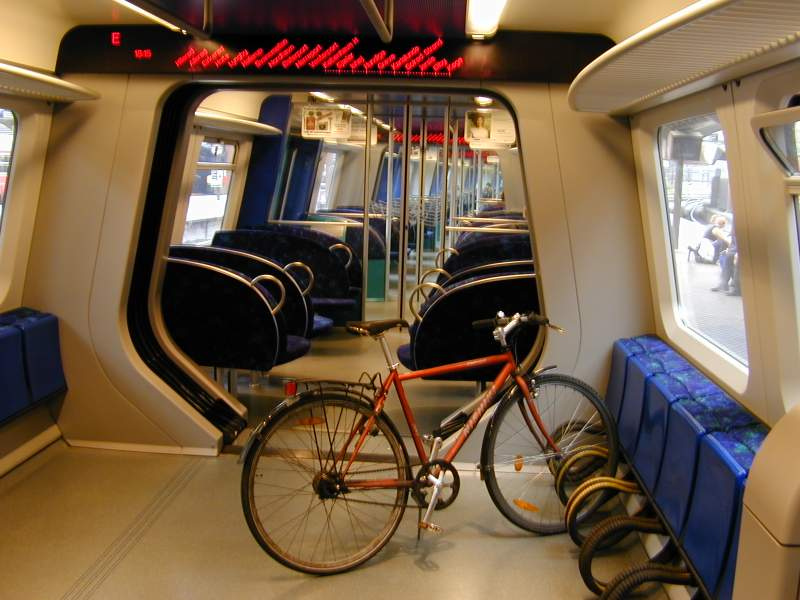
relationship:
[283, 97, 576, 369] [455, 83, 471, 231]
row of pole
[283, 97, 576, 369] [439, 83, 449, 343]
row of pole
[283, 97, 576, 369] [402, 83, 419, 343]
row of pole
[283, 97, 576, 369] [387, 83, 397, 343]
row of pole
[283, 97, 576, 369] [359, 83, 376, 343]
row of pole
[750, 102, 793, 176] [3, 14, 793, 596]
window on train